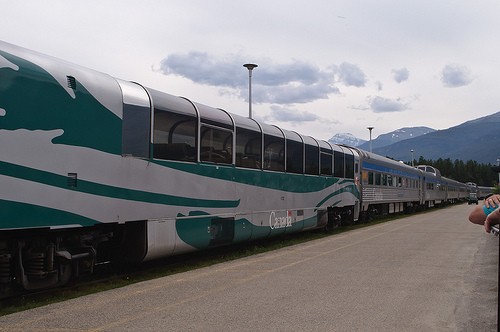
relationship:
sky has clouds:
[4, 1, 498, 144] [160, 49, 473, 130]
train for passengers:
[0, 40, 491, 293] [459, 187, 496, 238]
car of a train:
[1, 42, 363, 296] [0, 40, 491, 293]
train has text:
[0, 40, 491, 293] [264, 206, 297, 232]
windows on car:
[139, 77, 354, 179] [1, 42, 363, 296]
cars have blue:
[358, 142, 498, 214] [364, 158, 470, 188]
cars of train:
[358, 142, 498, 214] [0, 40, 491, 293]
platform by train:
[4, 194, 500, 329] [0, 40, 491, 293]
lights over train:
[243, 58, 419, 156] [0, 40, 491, 293]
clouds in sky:
[160, 49, 473, 130] [4, 1, 498, 144]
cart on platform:
[466, 190, 480, 206] [4, 194, 500, 329]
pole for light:
[243, 62, 258, 120] [243, 60, 257, 74]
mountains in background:
[327, 111, 500, 165] [1, 7, 497, 202]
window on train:
[191, 96, 233, 166] [0, 40, 491, 293]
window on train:
[317, 132, 335, 176] [0, 40, 491, 293]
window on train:
[262, 112, 285, 174] [0, 40, 491, 293]